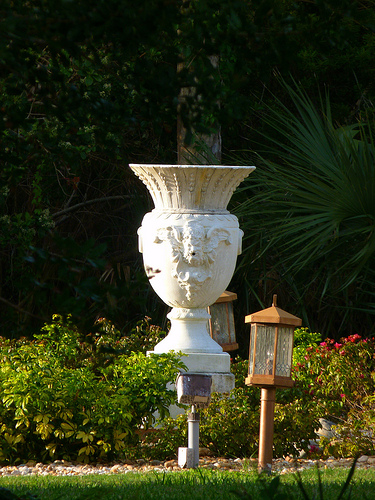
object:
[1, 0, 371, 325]
tree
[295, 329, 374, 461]
plants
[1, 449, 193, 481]
gravel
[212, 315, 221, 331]
lightbulb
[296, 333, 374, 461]
bush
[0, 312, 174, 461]
bush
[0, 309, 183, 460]
group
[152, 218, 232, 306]
carving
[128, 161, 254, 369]
stone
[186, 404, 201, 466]
metal stand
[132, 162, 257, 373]
birdbath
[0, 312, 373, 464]
shrubbery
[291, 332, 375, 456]
flowers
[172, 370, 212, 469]
light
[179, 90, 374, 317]
palm tree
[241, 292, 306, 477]
brown accessory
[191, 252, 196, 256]
hole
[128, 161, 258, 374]
sculture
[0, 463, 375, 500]
grass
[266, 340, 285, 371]
bulb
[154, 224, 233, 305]
face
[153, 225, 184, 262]
wing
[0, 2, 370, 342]
forest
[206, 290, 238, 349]
bronze light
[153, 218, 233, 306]
pattern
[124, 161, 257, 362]
vase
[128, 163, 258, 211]
mouth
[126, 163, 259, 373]
urn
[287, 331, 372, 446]
leaves